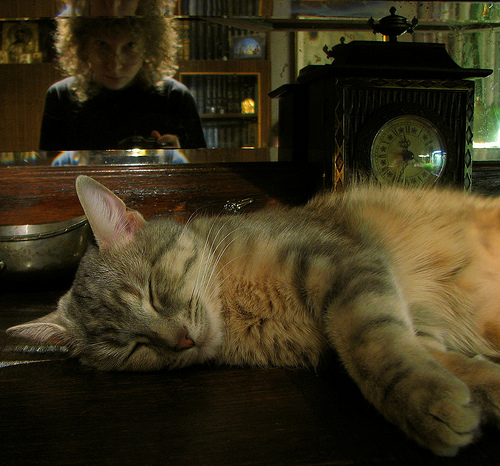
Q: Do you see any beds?
A: No, there are no beds.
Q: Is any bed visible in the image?
A: No, there are no beds.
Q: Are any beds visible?
A: No, there are no beds.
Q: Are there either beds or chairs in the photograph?
A: No, there are no beds or chairs.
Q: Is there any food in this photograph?
A: No, there is no food.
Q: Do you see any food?
A: No, there is no food.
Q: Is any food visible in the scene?
A: No, there is no food.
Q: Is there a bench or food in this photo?
A: No, there are no food or benches.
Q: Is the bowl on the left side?
A: Yes, the bowl is on the left of the image.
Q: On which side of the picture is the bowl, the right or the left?
A: The bowl is on the left of the image.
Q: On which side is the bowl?
A: The bowl is on the left of the image.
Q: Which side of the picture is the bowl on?
A: The bowl is on the left of the image.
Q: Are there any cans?
A: No, there are no cans.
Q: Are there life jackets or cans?
A: No, there are no cans or life jackets.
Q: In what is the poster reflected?
A: The poster is reflected in the mirror.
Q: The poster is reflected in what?
A: The poster is reflected in the mirror.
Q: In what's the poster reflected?
A: The poster is reflected in the mirror.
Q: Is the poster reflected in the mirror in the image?
A: Yes, the poster is reflected in the mirror.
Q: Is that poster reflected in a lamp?
A: No, the poster is reflected in the mirror.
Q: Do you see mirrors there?
A: Yes, there is a mirror.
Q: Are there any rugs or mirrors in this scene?
A: Yes, there is a mirror.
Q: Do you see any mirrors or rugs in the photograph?
A: Yes, there is a mirror.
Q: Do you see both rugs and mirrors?
A: No, there is a mirror but no rugs.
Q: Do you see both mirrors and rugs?
A: No, there is a mirror but no rugs.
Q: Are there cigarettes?
A: No, there are no cigarettes.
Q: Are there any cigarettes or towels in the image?
A: No, there are no cigarettes or towels.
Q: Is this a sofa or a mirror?
A: This is a mirror.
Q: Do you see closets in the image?
A: No, there are no closets.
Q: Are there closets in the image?
A: No, there are no closets.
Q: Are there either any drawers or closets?
A: No, there are no closets or drawers.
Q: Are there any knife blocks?
A: No, there are no knife blocks.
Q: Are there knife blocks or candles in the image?
A: No, there are no knife blocks or candles.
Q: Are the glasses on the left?
A: Yes, the glasses are on the left of the image.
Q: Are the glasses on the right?
A: No, the glasses are on the left of the image.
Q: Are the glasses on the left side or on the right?
A: The glasses are on the left of the image.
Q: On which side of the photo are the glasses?
A: The glasses are on the left of the image.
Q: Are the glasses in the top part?
A: Yes, the glasses are in the top of the image.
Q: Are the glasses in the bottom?
A: No, the glasses are in the top of the image.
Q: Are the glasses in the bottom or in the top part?
A: The glasses are in the top of the image.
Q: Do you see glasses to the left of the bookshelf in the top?
A: Yes, there are glasses to the left of the bookshelf.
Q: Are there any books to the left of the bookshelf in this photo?
A: No, there are glasses to the left of the bookshelf.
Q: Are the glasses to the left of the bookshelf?
A: Yes, the glasses are to the left of the bookshelf.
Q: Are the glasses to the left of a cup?
A: No, the glasses are to the left of the bookshelf.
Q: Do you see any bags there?
A: No, there are no bags.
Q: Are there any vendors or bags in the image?
A: No, there are no bags or vendors.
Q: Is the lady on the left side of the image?
A: Yes, the lady is on the left of the image.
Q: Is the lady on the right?
A: No, the lady is on the left of the image.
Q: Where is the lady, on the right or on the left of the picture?
A: The lady is on the left of the image.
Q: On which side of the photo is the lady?
A: The lady is on the left of the image.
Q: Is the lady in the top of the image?
A: Yes, the lady is in the top of the image.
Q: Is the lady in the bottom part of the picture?
A: No, the lady is in the top of the image.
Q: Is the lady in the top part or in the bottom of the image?
A: The lady is in the top of the image.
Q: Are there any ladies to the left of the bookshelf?
A: Yes, there is a lady to the left of the bookshelf.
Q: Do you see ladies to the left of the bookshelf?
A: Yes, there is a lady to the left of the bookshelf.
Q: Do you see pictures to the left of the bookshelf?
A: No, there is a lady to the left of the bookshelf.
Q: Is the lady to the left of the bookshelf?
A: Yes, the lady is to the left of the bookshelf.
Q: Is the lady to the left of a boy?
A: No, the lady is to the left of the bookshelf.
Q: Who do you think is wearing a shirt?
A: The lady is wearing a shirt.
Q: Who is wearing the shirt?
A: The lady is wearing a shirt.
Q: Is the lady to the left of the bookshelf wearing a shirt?
A: Yes, the lady is wearing a shirt.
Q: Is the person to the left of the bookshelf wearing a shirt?
A: Yes, the lady is wearing a shirt.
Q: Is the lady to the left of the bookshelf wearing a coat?
A: No, the lady is wearing a shirt.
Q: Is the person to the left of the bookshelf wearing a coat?
A: No, the lady is wearing a shirt.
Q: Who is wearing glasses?
A: The lady is wearing glasses.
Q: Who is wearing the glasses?
A: The lady is wearing glasses.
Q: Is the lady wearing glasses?
A: Yes, the lady is wearing glasses.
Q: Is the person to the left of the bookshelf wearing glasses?
A: Yes, the lady is wearing glasses.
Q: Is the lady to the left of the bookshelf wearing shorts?
A: No, the lady is wearing glasses.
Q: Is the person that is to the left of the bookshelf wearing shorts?
A: No, the lady is wearing glasses.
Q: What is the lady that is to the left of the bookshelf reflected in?
A: The lady is reflected in the mirror.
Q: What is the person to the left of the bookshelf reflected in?
A: The lady is reflected in the mirror.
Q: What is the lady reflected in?
A: The lady is reflected in the mirror.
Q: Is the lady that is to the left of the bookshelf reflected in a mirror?
A: Yes, the lady is reflected in a mirror.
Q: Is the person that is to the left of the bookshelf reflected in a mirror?
A: Yes, the lady is reflected in a mirror.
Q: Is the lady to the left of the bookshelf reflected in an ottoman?
A: No, the lady is reflected in a mirror.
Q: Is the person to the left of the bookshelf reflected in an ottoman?
A: No, the lady is reflected in a mirror.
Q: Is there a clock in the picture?
A: Yes, there is a clock.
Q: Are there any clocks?
A: Yes, there is a clock.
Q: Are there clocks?
A: Yes, there is a clock.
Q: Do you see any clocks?
A: Yes, there is a clock.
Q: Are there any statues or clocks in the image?
A: Yes, there is a clock.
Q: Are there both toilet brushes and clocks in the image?
A: No, there is a clock but no toilet brushes.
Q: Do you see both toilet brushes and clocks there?
A: No, there is a clock but no toilet brushes.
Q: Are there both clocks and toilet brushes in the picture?
A: No, there is a clock but no toilet brushes.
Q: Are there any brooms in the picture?
A: No, there are no brooms.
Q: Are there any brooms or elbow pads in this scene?
A: No, there are no brooms or elbow pads.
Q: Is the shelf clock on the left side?
A: No, the clock is on the right of the image.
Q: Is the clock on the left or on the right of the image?
A: The clock is on the right of the image.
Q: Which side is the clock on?
A: The clock is on the right of the image.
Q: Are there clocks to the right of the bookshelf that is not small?
A: Yes, there is a clock to the right of the bookshelf.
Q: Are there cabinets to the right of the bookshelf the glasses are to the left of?
A: No, there is a clock to the right of the bookshelf.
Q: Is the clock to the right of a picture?
A: No, the clock is to the right of a bookshelf.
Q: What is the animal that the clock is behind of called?
A: The animal is a cat.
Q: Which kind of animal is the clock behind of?
A: The clock is behind the cat.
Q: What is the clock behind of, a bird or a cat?
A: The clock is behind a cat.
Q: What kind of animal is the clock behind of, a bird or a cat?
A: The clock is behind a cat.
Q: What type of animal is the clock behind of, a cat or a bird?
A: The clock is behind a cat.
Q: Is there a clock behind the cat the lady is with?
A: Yes, there is a clock behind the cat.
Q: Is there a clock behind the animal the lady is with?
A: Yes, there is a clock behind the cat.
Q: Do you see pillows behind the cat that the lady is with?
A: No, there is a clock behind the cat.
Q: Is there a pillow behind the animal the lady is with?
A: No, there is a clock behind the cat.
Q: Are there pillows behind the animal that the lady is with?
A: No, there is a clock behind the cat.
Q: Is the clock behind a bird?
A: No, the clock is behind the cat.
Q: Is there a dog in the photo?
A: No, there are no dogs.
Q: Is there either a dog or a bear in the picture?
A: No, there are no dogs or bears.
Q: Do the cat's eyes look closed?
A: Yes, the eyes are closed.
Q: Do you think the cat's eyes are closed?
A: Yes, the eyes are closed.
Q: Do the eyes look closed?
A: Yes, the eyes are closed.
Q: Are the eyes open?
A: No, the eyes are closed.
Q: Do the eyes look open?
A: No, the eyes are closed.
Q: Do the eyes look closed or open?
A: The eyes are closed.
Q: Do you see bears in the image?
A: No, there are no bears.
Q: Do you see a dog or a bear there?
A: No, there are no bears or dogs.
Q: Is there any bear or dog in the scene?
A: No, there are no bears or dogs.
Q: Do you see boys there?
A: No, there are no boys.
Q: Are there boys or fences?
A: No, there are no boys or fences.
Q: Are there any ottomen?
A: No, there are no ottomen.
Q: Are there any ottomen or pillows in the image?
A: No, there are no ottomen or pillows.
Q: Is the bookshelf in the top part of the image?
A: Yes, the bookshelf is in the top of the image.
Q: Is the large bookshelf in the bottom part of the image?
A: No, the bookshelf is in the top of the image.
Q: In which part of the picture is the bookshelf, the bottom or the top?
A: The bookshelf is in the top of the image.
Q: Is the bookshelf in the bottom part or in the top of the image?
A: The bookshelf is in the top of the image.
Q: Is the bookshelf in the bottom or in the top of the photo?
A: The bookshelf is in the top of the image.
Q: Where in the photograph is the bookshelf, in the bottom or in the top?
A: The bookshelf is in the top of the image.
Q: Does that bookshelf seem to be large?
A: Yes, the bookshelf is large.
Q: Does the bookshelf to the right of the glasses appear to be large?
A: Yes, the bookshelf is large.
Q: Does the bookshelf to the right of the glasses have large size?
A: Yes, the bookshelf is large.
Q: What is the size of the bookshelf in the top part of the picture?
A: The bookshelf is large.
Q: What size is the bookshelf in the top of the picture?
A: The bookshelf is large.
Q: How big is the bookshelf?
A: The bookshelf is large.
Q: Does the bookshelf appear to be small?
A: No, the bookshelf is large.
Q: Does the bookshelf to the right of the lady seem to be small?
A: No, the bookshelf is large.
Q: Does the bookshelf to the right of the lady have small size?
A: No, the bookshelf is large.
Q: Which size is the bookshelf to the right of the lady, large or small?
A: The bookshelf is large.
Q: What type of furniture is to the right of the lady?
A: The piece of furniture is a bookshelf.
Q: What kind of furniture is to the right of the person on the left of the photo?
A: The piece of furniture is a bookshelf.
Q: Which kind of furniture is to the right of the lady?
A: The piece of furniture is a bookshelf.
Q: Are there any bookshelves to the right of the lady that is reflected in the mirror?
A: Yes, there is a bookshelf to the right of the lady.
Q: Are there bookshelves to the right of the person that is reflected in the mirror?
A: Yes, there is a bookshelf to the right of the lady.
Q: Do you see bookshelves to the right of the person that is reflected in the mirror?
A: Yes, there is a bookshelf to the right of the lady.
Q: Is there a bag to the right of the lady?
A: No, there is a bookshelf to the right of the lady.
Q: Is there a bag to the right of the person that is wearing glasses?
A: No, there is a bookshelf to the right of the lady.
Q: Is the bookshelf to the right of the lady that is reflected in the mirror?
A: Yes, the bookshelf is to the right of the lady.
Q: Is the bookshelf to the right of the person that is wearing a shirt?
A: Yes, the bookshelf is to the right of the lady.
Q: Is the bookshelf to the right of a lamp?
A: No, the bookshelf is to the right of the lady.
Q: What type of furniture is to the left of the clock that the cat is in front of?
A: The piece of furniture is a bookshelf.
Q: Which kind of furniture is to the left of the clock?
A: The piece of furniture is a bookshelf.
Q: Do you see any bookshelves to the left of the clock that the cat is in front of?
A: Yes, there is a bookshelf to the left of the clock.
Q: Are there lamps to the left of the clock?
A: No, there is a bookshelf to the left of the clock.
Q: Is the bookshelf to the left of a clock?
A: Yes, the bookshelf is to the left of a clock.